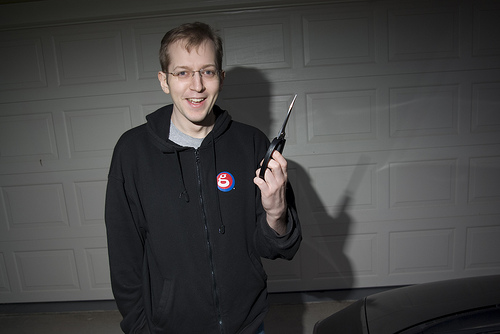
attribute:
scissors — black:
[257, 93, 299, 180]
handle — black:
[260, 134, 285, 181]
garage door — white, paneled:
[0, 1, 499, 304]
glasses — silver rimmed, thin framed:
[162, 66, 220, 79]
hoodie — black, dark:
[105, 100, 303, 333]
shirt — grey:
[168, 118, 203, 150]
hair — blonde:
[157, 22, 223, 82]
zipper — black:
[194, 146, 224, 334]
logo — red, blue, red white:
[214, 171, 237, 194]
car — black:
[314, 272, 499, 333]